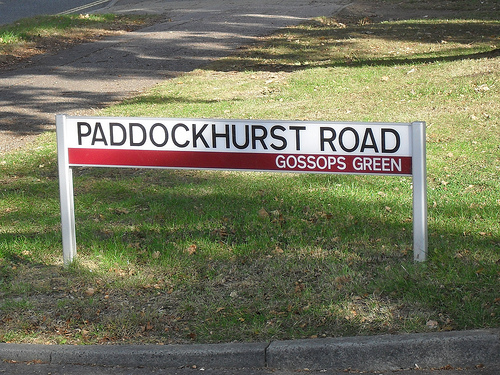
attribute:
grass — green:
[4, 4, 491, 342]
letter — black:
[73, 122, 91, 149]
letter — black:
[89, 119, 106, 149]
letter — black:
[104, 122, 127, 147]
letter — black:
[127, 122, 147, 148]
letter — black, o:
[147, 123, 169, 147]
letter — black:
[169, 122, 191, 146]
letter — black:
[191, 125, 211, 150]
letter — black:
[210, 123, 232, 147]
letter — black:
[231, 124, 251, 149]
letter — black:
[252, 127, 270, 154]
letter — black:
[268, 122, 286, 152]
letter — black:
[271, 124, 288, 156]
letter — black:
[288, 126, 308, 149]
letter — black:
[316, 129, 336, 151]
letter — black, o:
[339, 126, 360, 153]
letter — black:
[360, 125, 377, 155]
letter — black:
[380, 130, 399, 153]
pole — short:
[410, 121, 430, 266]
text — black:
[65, 116, 418, 175]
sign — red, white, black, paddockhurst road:
[52, 106, 431, 266]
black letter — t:
[285, 125, 309, 150]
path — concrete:
[0, 0, 349, 157]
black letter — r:
[250, 122, 267, 152]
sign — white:
[53, 114, 430, 187]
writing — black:
[319, 119, 404, 170]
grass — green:
[393, 57, 461, 129]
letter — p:
[76, 120, 91, 145]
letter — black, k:
[190, 121, 209, 149]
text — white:
[273, 152, 405, 173]